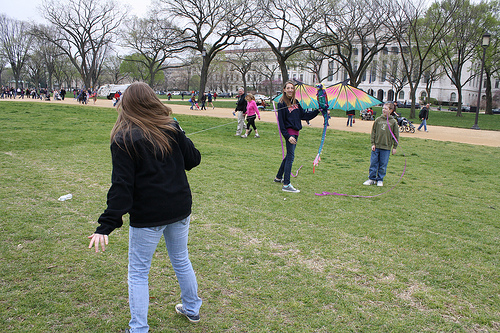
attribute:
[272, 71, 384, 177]
kite — dragon shaped, rainbow colored, big, colorful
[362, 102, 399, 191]
boy — standing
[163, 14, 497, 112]
building — large, white, old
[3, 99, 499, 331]
grass — dry, green, large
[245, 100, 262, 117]
jacket — pink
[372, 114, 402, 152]
sweatshirt — olive green, green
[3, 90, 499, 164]
walking path — dirt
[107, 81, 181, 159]
hair — brown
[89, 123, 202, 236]
jacket — black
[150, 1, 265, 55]
leaves — bare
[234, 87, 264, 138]
people — older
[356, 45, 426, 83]
columns — white